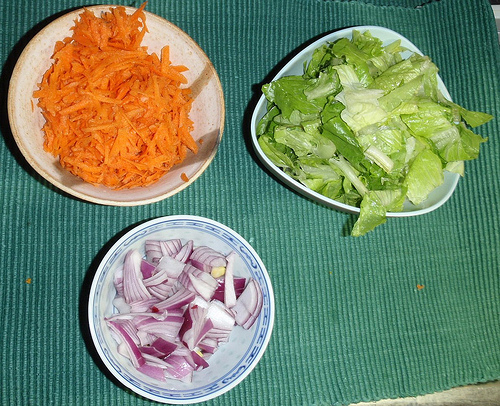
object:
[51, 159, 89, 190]
shadow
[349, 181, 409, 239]
lettuce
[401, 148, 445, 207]
lettuce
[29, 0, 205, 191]
ingredients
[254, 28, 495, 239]
ingredients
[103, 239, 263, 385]
ingredients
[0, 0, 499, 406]
cloth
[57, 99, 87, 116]
carrots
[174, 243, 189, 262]
onions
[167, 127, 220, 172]
shadow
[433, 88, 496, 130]
lettuce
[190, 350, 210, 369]
onions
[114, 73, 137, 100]
vegetables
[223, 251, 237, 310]
object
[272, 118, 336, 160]
object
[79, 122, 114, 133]
object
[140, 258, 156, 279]
onions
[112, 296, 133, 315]
onions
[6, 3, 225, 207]
bowl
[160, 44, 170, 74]
carrots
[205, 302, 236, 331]
onions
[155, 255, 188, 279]
onions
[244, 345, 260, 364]
trim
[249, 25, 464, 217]
bowl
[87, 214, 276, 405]
bowl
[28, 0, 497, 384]
trio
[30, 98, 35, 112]
pattern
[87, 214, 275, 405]
rim